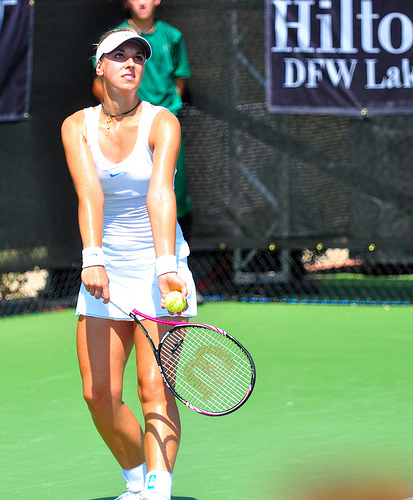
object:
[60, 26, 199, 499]
girl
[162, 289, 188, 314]
ball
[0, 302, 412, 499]
court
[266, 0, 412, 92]
sign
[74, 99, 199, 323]
outfit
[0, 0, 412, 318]
fence